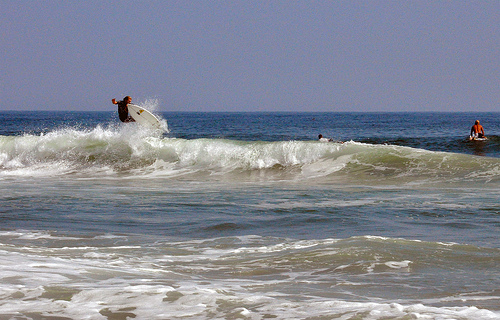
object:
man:
[110, 95, 133, 124]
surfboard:
[125, 102, 163, 132]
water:
[0, 109, 499, 319]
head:
[121, 95, 132, 102]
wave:
[332, 228, 439, 248]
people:
[313, 134, 341, 144]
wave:
[0, 116, 499, 188]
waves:
[0, 228, 499, 319]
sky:
[0, 0, 499, 113]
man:
[468, 118, 488, 141]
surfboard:
[473, 135, 488, 143]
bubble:
[0, 229, 499, 320]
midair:
[105, 90, 150, 125]